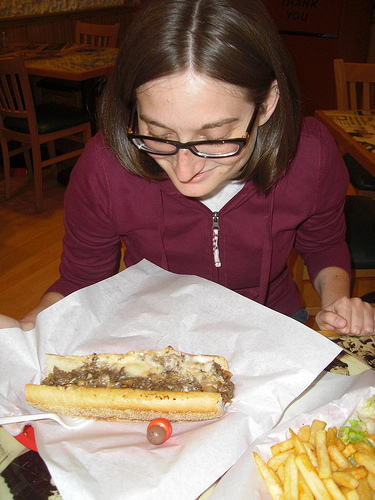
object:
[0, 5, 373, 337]
woman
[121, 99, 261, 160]
glasses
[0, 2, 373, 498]
photo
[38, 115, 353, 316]
sweater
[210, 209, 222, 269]
zipper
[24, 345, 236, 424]
chhesesteak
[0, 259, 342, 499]
paper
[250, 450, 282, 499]
fries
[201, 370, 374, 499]
paper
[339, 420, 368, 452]
lettuce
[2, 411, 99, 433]
fork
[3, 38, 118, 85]
table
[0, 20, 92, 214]
chairs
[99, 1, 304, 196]
hair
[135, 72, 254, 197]
face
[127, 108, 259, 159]
frames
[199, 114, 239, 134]
eyebrows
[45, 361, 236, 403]
beef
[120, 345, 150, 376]
cheese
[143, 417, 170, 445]
object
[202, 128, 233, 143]
eyes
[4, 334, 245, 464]
plate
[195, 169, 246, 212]
t-shirt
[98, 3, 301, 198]
head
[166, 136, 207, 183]
nose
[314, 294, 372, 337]
hand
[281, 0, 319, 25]
sign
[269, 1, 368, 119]
door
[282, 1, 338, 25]
thank you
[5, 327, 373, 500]
table